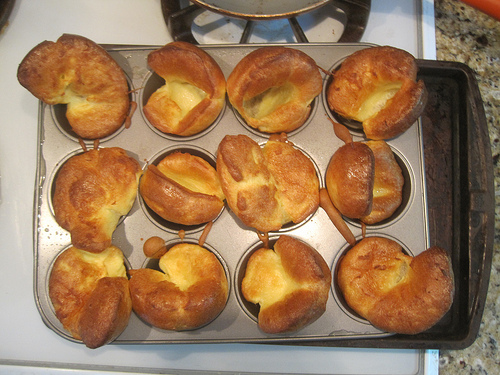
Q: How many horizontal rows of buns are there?
A: 3.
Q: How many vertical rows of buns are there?
A: 4.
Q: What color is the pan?
A: Silver.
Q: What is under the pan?
A: Baking sheet.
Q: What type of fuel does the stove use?
A: Gas.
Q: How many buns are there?
A: 12.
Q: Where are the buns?
A: In the pan.